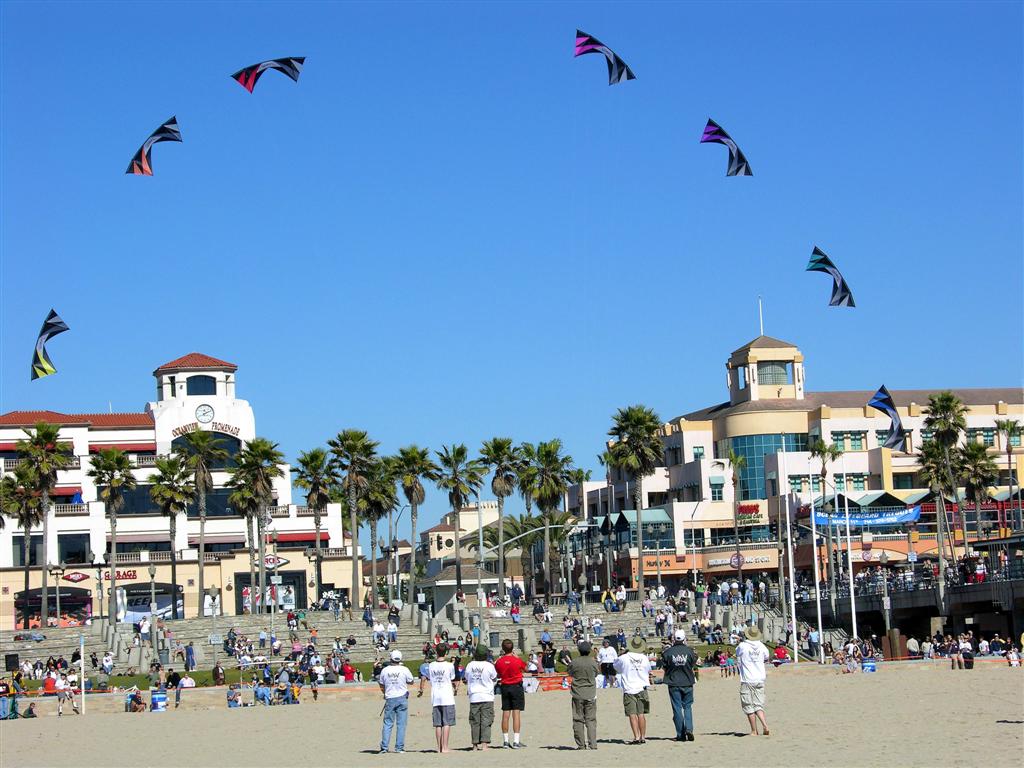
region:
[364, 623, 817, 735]
There are eight people watching the kites flying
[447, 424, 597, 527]
Tall palm trees are next to the building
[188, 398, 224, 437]
A large clock is set in the top of the building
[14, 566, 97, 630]
A retail store is on the bottom floor of this building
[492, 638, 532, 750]
A man in a red shirt and black shorts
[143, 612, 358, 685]
A stadium with some people observing the activities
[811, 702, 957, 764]
A sandy ground for multi-use of activities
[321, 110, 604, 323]
The sky is clear with no clouds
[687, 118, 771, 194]
a kite in the sky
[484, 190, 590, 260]
the sky is clear and blue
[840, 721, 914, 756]
the sand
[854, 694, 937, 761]
the sand is brown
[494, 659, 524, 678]
a red shirt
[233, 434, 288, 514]
a palm tree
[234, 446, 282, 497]
tree is green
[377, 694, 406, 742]
man wearing pants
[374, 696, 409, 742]
pants are light blue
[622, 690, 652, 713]
shorts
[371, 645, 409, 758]
person standing on beach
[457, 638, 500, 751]
person standing on beach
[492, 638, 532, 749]
person standing on beach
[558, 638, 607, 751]
person standing on beach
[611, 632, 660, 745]
person standing on beach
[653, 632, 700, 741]
person standing on beach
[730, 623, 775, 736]
person standing on beach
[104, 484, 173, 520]
window on building facing beach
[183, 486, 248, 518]
window on building facing beach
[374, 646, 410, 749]
spectator watching kite show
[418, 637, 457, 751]
spectator watching kite show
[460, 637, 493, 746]
spectator watching kite show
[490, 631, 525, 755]
spectator watching kite show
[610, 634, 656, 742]
spectator watching kite show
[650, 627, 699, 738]
spectator watching kite show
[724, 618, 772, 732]
spectator watching kite show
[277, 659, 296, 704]
spectator watching kite show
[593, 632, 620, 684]
spectator watching kite show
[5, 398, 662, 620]
line of palm trees along the sidewalk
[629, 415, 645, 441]
green leaves on the tree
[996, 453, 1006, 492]
green leaves on the tree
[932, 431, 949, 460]
green leaves on the tree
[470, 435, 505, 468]
green leaves on the tree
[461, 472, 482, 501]
green leaves on the tree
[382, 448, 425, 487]
green leaves on the tree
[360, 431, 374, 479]
green leaves on the tree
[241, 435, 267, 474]
green leaves on the tree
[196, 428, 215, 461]
green leaves on the tree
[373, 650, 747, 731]
people standing in the sand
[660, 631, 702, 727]
a person in a black shirt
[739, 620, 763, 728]
a person in a white shirt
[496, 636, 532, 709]
a person in a red shirt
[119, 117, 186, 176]
a kite in the sky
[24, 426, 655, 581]
a line of palm trees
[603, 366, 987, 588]
a large building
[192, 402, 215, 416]
a clock on the building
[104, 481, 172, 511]
a window on the building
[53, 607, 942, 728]
people standing in front of the building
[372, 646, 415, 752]
A person is standing up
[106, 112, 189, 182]
black and pink kite in the sky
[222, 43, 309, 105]
black and pink kite in the sky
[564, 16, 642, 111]
black and pink kite in the sky